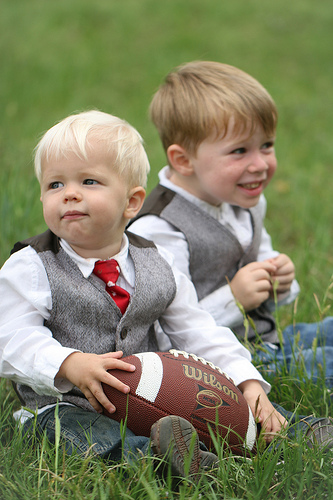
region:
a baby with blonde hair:
[6, 109, 160, 252]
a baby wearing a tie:
[4, 111, 199, 375]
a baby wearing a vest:
[3, 128, 183, 375]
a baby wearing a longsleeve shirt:
[9, 121, 265, 425]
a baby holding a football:
[3, 118, 253, 498]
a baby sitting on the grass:
[7, 120, 217, 499]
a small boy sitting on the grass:
[127, 58, 315, 391]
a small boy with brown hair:
[134, 60, 296, 204]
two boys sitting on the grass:
[27, 71, 314, 461]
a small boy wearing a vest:
[131, 74, 310, 336]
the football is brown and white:
[89, 337, 262, 459]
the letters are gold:
[168, 361, 241, 405]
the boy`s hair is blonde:
[23, 96, 150, 211]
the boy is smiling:
[163, 52, 280, 212]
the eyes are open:
[29, 171, 115, 196]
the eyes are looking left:
[20, 166, 111, 196]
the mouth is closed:
[36, 203, 97, 226]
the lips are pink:
[50, 203, 93, 225]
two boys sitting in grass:
[0, 52, 329, 489]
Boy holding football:
[2, 109, 264, 490]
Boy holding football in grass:
[4, 100, 288, 483]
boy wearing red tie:
[2, 102, 293, 499]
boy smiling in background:
[135, 61, 307, 222]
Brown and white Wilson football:
[92, 342, 266, 465]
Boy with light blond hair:
[2, 108, 292, 483]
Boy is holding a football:
[1, 105, 294, 479]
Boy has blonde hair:
[29, 107, 152, 245]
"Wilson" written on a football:
[177, 358, 240, 408]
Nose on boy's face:
[246, 149, 272, 179]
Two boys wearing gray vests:
[1, 57, 307, 410]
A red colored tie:
[90, 256, 136, 318]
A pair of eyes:
[45, 172, 103, 193]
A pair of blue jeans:
[249, 310, 330, 388]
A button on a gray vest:
[114, 318, 133, 344]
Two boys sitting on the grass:
[0, 53, 331, 498]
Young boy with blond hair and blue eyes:
[1, 106, 331, 484]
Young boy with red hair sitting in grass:
[125, 58, 331, 391]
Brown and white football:
[96, 348, 259, 457]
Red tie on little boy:
[91, 257, 131, 318]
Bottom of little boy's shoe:
[151, 413, 222, 494]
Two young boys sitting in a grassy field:
[1, 58, 332, 491]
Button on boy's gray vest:
[119, 325, 128, 338]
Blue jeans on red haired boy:
[254, 315, 331, 391]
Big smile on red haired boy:
[237, 178, 266, 198]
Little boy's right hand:
[56, 348, 136, 414]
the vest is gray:
[13, 230, 182, 413]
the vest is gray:
[23, 232, 174, 407]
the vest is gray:
[13, 217, 175, 412]